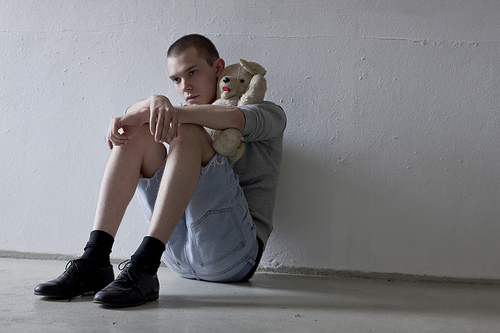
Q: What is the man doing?
A: The man is sitting on the floor.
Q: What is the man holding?
A: The man is holding a teddy bear.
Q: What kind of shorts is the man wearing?
A: The man is wearing light blue denim shorts.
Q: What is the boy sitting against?
A: A wall.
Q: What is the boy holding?
A: A teddy bear.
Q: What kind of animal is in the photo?
A: Bear.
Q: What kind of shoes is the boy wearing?
A: Black dress shoes.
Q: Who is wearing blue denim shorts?
A: The boy.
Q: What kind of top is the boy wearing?
A: Gray long sleeve.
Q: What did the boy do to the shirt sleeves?
A: Pushed them up past his elbows.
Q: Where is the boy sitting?
A: On the floor.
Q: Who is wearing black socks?
A: The boy.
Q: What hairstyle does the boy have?
A: Buzz cut.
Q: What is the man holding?
A: Bear.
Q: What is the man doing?
A: Sitting.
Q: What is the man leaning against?
A: Wall.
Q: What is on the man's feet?
A: Shoes.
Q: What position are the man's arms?
A: Crossed.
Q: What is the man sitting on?
A: Floor.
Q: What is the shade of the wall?
A: White.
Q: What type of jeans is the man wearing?
A: Blue.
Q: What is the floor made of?
A: Concrete.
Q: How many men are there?
A: One.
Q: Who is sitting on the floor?
A: The man.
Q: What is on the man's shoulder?
A: A teddy bear.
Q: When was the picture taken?
A: Daytime.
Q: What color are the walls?
A: White.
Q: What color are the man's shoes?
A: Black.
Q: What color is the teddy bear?
A: Brown.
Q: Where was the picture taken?
A: In an urban building.